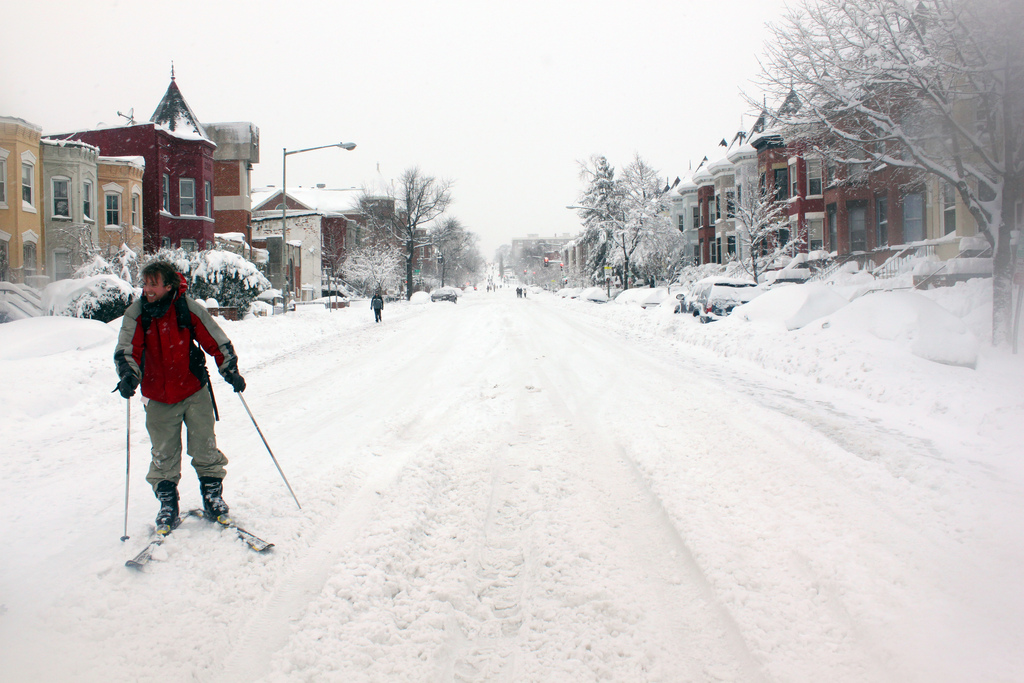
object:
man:
[112, 261, 247, 532]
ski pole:
[120, 397, 131, 543]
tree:
[737, 0, 1024, 343]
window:
[50, 175, 74, 223]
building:
[0, 113, 145, 286]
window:
[807, 157, 824, 200]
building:
[32, 57, 221, 260]